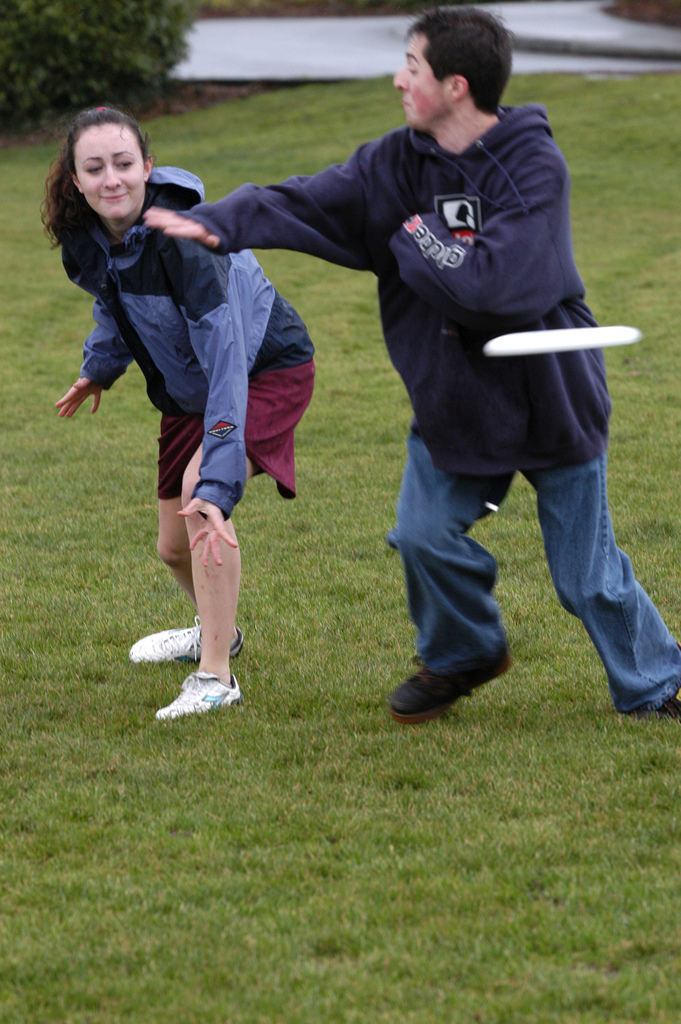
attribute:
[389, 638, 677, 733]
shoes — black, brown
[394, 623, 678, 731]
shoes — brown, black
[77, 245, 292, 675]
lady — playing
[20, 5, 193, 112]
bush — green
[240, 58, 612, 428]
hoodie — blue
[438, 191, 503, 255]
loogo — white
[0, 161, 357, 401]
jacket — blue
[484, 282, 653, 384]
frisbee — white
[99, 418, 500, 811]
grass — green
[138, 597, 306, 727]
shoes — white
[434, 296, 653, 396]
frisbee — white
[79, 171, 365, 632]
woman — playing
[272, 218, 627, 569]
man — playing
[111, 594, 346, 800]
shoes — white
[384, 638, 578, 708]
shoe — black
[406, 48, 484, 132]
cheeks — red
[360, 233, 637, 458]
hoodie — blue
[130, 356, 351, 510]
skirt — red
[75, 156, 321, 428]
jacket — blue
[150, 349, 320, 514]
shorts — red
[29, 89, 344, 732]
woman — young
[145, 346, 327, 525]
shorts — red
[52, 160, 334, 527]
jacket — blue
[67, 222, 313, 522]
jacket — blue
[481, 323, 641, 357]
frisbee — white